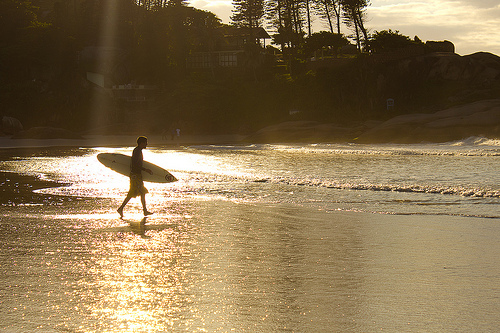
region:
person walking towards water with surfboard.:
[28, 17, 473, 302]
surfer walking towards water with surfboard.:
[20, 36, 470, 288]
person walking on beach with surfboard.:
[31, 30, 431, 285]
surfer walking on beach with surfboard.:
[32, 47, 368, 277]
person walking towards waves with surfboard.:
[31, 50, 426, 291]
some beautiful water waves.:
[195, 111, 466, 216]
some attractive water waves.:
[187, 135, 467, 220]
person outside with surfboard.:
[90, 121, 182, 221]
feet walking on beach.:
[100, 200, 156, 241]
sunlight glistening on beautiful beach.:
[26, 222, 213, 324]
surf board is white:
[86, 144, 188, 189]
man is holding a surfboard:
[76, 127, 193, 237]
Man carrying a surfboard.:
[63, 124, 172, 246]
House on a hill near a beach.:
[157, 12, 459, 79]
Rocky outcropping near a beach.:
[361, 39, 498, 94]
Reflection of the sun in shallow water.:
[54, 139, 234, 219]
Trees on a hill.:
[236, 0, 387, 54]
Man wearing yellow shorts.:
[118, 127, 156, 222]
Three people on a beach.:
[151, 123, 205, 148]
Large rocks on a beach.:
[0, 115, 109, 143]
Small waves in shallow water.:
[221, 141, 498, 221]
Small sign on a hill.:
[373, 92, 408, 119]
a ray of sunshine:
[83, 4, 123, 202]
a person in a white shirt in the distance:
[172, 124, 186, 142]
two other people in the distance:
[156, 123, 171, 144]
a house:
[173, 15, 278, 92]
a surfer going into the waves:
[95, 127, 190, 225]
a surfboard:
[91, 153, 178, 190]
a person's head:
[129, 124, 154, 154]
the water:
[10, 144, 498, 331]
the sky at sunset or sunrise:
[138, 0, 498, 81]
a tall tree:
[345, 0, 378, 62]